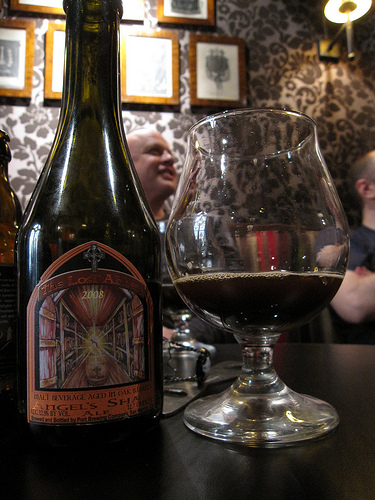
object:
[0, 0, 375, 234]
wallpaper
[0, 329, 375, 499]
table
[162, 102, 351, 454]
glass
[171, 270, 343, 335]
wine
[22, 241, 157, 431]
label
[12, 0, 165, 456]
bottle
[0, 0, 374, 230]
wall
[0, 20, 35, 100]
picture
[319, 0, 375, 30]
light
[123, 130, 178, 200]
head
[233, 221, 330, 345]
chair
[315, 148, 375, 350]
man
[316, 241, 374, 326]
arm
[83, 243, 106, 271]
cross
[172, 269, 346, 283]
bubble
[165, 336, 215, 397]
bottle opener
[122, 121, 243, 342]
man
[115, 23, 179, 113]
picture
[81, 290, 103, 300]
date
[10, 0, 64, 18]
picture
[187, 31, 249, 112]
frame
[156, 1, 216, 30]
picture